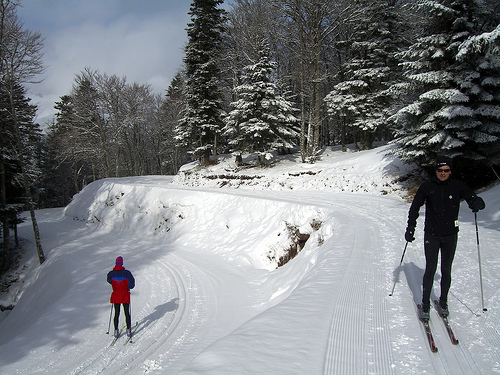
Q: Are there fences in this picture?
A: No, there are no fences.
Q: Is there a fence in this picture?
A: No, there are no fences.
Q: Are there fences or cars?
A: No, there are no fences or cars.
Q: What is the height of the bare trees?
A: The trees are tall.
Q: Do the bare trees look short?
A: No, the trees are tall.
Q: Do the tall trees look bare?
A: Yes, the trees are bare.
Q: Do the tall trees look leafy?
A: No, the trees are bare.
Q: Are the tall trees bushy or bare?
A: The trees are bare.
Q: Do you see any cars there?
A: No, there are no cars.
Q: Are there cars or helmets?
A: No, there are no cars or helmets.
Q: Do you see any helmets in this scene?
A: No, there are no helmets.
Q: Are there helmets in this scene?
A: No, there are no helmets.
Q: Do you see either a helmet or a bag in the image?
A: No, there are no helmets or bags.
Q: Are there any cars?
A: No, there are no cars.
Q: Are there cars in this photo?
A: No, there are no cars.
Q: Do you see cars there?
A: No, there are no cars.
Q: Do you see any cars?
A: No, there are no cars.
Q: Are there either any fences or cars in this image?
A: No, there are no cars or fences.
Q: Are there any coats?
A: Yes, there is a coat.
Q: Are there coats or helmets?
A: Yes, there is a coat.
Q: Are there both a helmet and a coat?
A: No, there is a coat but no helmets.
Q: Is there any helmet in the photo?
A: No, there are no helmets.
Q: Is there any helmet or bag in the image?
A: No, there are no helmets or bags.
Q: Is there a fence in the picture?
A: No, there are no fences.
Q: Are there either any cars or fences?
A: No, there are no fences or cars.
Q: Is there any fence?
A: No, there are no fences.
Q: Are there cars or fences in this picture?
A: No, there are no fences or cars.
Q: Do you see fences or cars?
A: No, there are no fences or cars.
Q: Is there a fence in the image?
A: No, there are no fences.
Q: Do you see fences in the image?
A: No, there are no fences.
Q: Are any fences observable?
A: No, there are no fences.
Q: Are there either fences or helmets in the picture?
A: No, there are no fences or helmets.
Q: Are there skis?
A: Yes, there are skis.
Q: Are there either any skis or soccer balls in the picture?
A: Yes, there are skis.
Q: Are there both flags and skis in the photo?
A: No, there are skis but no flags.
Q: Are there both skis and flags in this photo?
A: No, there are skis but no flags.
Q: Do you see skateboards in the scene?
A: No, there are no skateboards.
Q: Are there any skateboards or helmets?
A: No, there are no skateboards or helmets.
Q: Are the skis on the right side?
A: Yes, the skis are on the right of the image.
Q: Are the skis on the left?
A: No, the skis are on the right of the image.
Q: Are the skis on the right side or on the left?
A: The skis are on the right of the image.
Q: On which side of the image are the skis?
A: The skis are on the right of the image.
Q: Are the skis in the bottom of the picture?
A: Yes, the skis are in the bottom of the image.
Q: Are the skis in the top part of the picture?
A: No, the skis are in the bottom of the image.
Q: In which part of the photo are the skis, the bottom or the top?
A: The skis are in the bottom of the image.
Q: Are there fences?
A: No, there are no fences.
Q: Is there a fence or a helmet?
A: No, there are no fences or helmets.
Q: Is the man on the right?
A: Yes, the man is on the right of the image.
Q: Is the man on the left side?
A: No, the man is on the right of the image.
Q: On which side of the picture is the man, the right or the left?
A: The man is on the right of the image.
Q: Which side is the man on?
A: The man is on the right of the image.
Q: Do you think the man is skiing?
A: Yes, the man is skiing.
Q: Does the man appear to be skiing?
A: Yes, the man is skiing.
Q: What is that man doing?
A: The man is skiing.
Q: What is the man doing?
A: The man is skiing.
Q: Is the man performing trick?
A: No, the man is skiing.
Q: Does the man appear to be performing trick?
A: No, the man is skiing.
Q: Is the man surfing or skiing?
A: The man is skiing.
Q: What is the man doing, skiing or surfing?
A: The man is skiing.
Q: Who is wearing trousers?
A: The man is wearing trousers.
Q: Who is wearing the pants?
A: The man is wearing trousers.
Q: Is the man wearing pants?
A: Yes, the man is wearing pants.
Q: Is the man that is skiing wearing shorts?
A: No, the man is wearing pants.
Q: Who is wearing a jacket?
A: The man is wearing a jacket.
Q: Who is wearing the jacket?
A: The man is wearing a jacket.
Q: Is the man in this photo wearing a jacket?
A: Yes, the man is wearing a jacket.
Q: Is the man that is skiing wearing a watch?
A: No, the man is wearing a jacket.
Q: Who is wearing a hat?
A: The man is wearing a hat.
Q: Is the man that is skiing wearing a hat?
A: Yes, the man is wearing a hat.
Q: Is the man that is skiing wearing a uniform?
A: No, the man is wearing a hat.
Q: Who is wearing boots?
A: The man is wearing boots.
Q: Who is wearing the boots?
A: The man is wearing boots.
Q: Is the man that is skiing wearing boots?
A: Yes, the man is wearing boots.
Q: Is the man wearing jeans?
A: No, the man is wearing boots.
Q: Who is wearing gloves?
A: The man is wearing gloves.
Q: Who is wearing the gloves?
A: The man is wearing gloves.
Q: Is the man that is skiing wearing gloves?
A: Yes, the man is wearing gloves.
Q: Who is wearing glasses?
A: The man is wearing glasses.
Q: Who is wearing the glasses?
A: The man is wearing glasses.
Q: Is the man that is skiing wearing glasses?
A: Yes, the man is wearing glasses.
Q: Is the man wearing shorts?
A: No, the man is wearing glasses.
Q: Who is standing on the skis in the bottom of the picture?
A: The man is standing on the skis.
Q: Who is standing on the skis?
A: The man is standing on the skis.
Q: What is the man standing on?
A: The man is standing on the skis.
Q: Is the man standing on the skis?
A: Yes, the man is standing on the skis.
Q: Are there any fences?
A: No, there are no fences.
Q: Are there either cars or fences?
A: No, there are no fences or cars.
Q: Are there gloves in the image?
A: Yes, there are gloves.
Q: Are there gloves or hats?
A: Yes, there are gloves.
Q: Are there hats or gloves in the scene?
A: Yes, there are gloves.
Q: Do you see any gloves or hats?
A: Yes, there are gloves.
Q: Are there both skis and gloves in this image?
A: Yes, there are both gloves and skis.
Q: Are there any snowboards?
A: No, there are no snowboards.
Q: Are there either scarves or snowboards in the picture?
A: No, there are no snowboards or scarves.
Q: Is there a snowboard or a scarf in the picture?
A: No, there are no snowboards or scarves.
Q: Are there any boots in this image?
A: Yes, there are boots.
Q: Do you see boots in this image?
A: Yes, there are boots.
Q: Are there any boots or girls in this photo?
A: Yes, there are boots.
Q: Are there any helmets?
A: No, there are no helmets.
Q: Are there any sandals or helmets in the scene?
A: No, there are no helmets or sandals.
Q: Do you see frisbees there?
A: No, there are no frisbees.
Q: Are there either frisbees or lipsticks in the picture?
A: No, there are no frisbees or lipsticks.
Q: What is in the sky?
A: The clouds are in the sky.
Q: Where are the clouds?
A: The clouds are in the sky.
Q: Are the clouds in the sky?
A: Yes, the clouds are in the sky.